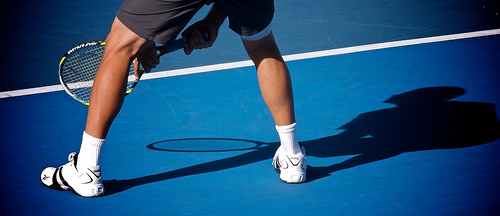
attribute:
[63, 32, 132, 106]
racket — here, held, tennis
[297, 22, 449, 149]
court — blue, tennis, here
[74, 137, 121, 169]
sock — here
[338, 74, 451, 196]
shadow — behind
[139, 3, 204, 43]
shorts — black, worn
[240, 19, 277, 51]
wrap — around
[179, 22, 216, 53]
hand — holding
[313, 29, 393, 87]
line — white, separating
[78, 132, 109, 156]
socks — white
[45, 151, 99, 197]
shoes — white, tennis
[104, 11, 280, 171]
player — standing, male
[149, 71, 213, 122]
surface — blue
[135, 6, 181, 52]
short — black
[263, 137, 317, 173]
foot — here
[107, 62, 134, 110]
leg — muscular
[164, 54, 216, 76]
lines — white